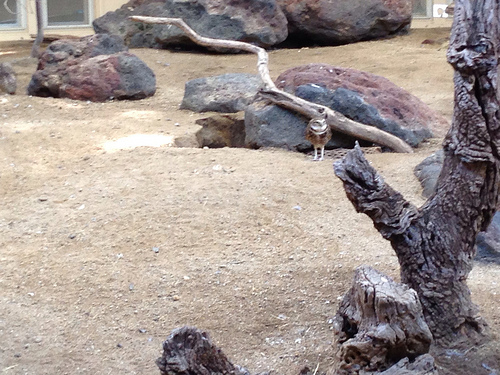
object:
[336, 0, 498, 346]
tree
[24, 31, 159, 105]
rock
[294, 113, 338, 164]
owl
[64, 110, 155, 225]
dirt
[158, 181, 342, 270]
ground